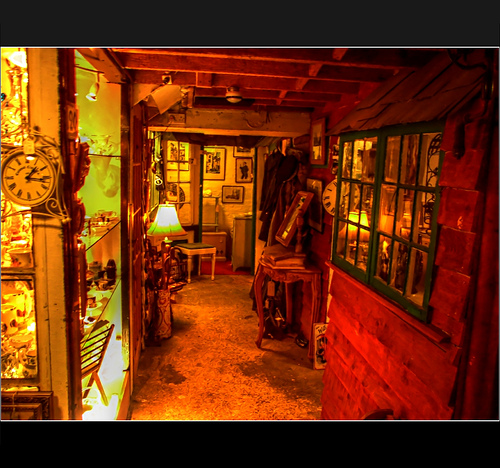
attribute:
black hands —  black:
[22, 167, 44, 183]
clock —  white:
[0, 147, 59, 207]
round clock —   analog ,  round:
[318, 172, 362, 222]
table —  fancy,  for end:
[249, 234, 349, 366]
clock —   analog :
[0, 117, 72, 220]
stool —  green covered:
[176, 240, 228, 295]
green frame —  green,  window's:
[331, 122, 445, 326]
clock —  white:
[6, 138, 83, 220]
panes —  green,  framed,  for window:
[352, 155, 482, 227]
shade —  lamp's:
[140, 204, 187, 236]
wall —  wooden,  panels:
[315, 326, 393, 416]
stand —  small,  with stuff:
[246, 168, 324, 351]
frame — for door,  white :
[31, 49, 66, 421]